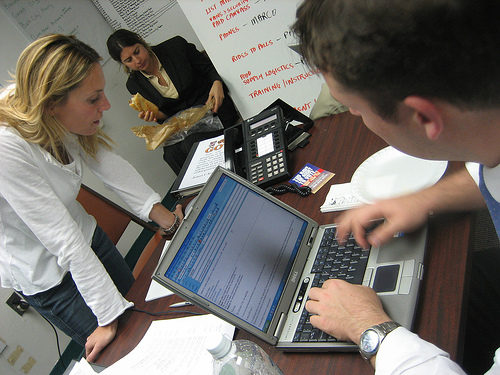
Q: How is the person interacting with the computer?
A: Typing.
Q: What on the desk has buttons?
A: Telephone.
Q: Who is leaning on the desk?
A: Woman.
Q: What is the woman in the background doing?
A: Eating.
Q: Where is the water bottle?
A: To the left of the man.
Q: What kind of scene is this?
A: Office environment.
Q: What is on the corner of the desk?
A: Black binder.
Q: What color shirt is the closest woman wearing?
A: White.